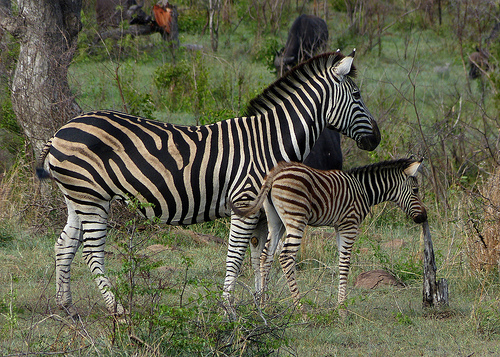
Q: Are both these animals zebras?
A: Yes, all the animals are zebras.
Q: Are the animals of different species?
A: No, all the animals are zebras.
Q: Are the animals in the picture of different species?
A: No, all the animals are zebras.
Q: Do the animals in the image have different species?
A: No, all the animals are zebras.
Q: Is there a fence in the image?
A: No, there are no fences.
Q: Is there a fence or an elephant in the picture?
A: No, there are no fences or elephants.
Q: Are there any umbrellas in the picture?
A: No, there are no umbrellas.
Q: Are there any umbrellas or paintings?
A: No, there are no umbrellas or paintings.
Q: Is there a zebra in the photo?
A: Yes, there is a zebra.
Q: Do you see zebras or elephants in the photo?
A: Yes, there is a zebra.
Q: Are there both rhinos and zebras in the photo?
A: No, there is a zebra but no rhinos.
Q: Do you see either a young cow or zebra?
A: Yes, there is a young zebra.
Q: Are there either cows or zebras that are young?
A: Yes, the zebra is young.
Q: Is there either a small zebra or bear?
A: Yes, there is a small zebra.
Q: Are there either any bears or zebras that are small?
A: Yes, the zebra is small.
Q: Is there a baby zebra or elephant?
A: Yes, there is a baby zebra.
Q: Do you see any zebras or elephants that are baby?
A: Yes, the zebra is a baby.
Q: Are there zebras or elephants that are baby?
A: Yes, the zebra is a baby.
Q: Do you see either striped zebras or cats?
A: Yes, there is a striped zebra.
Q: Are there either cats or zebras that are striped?
A: Yes, the zebra is striped.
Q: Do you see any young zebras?
A: Yes, there is a young zebra.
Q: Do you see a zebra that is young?
A: Yes, there is a zebra that is young.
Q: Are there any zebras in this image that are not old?
A: Yes, there is an young zebra.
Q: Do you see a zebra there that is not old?
A: Yes, there is an young zebra.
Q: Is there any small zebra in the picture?
A: Yes, there is a small zebra.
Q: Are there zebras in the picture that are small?
A: Yes, there is a zebra that is small.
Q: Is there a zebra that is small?
A: Yes, there is a zebra that is small.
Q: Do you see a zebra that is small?
A: Yes, there is a zebra that is small.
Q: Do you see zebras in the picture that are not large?
A: Yes, there is a small zebra.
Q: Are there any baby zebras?
A: Yes, there is a baby zebra.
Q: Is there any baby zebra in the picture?
A: Yes, there is a baby zebra.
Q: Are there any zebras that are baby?
A: Yes, there is a zebra that is a baby.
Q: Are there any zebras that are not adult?
A: Yes, there is an baby zebra.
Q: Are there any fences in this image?
A: No, there are no fences.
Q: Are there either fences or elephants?
A: No, there are no fences or elephants.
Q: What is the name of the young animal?
A: The animal is a zebra.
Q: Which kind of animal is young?
A: The animal is a zebra.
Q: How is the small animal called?
A: The animal is a zebra.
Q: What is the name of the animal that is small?
A: The animal is a zebra.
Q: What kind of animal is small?
A: The animal is a zebra.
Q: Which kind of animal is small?
A: The animal is a zebra.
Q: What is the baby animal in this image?
A: The animal is a zebra.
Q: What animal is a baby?
A: The animal is a zebra.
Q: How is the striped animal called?
A: The animal is a zebra.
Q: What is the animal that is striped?
A: The animal is a zebra.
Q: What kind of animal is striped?
A: The animal is a zebra.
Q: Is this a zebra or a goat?
A: This is a zebra.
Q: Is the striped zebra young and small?
A: Yes, the zebra is young and small.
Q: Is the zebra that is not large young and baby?
A: Yes, the zebra is young and baby.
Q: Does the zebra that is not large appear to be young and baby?
A: Yes, the zebra is young and baby.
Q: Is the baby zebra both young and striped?
A: Yes, the zebra is young and striped.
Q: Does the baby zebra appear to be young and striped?
A: Yes, the zebra is young and striped.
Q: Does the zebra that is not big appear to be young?
A: Yes, the zebra is young.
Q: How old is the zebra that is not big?
A: The zebra is young.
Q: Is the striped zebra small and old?
A: No, the zebra is small but young.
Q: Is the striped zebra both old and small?
A: No, the zebra is small but young.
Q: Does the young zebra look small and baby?
A: Yes, the zebra is small and baby.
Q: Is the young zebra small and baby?
A: Yes, the zebra is small and baby.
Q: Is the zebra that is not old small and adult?
A: No, the zebra is small but baby.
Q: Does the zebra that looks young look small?
A: Yes, the zebra is small.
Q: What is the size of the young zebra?
A: The zebra is small.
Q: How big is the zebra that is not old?
A: The zebra is small.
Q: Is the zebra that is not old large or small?
A: The zebra is small.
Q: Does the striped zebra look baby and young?
A: Yes, the zebra is a baby and young.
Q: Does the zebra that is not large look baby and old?
A: No, the zebra is a baby but young.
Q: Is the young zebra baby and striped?
A: Yes, the zebra is a baby and striped.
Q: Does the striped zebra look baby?
A: Yes, the zebra is a baby.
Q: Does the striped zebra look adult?
A: No, the zebra is a baby.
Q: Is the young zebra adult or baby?
A: The zebra is a baby.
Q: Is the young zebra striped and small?
A: Yes, the zebra is striped and small.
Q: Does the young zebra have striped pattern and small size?
A: Yes, the zebra is striped and small.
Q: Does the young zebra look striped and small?
A: Yes, the zebra is striped and small.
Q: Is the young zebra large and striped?
A: No, the zebra is striped but small.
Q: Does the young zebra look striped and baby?
A: Yes, the zebra is striped and baby.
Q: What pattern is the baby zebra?
A: The zebra is striped.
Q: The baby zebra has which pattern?
A: The zebra is striped.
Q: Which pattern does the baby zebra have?
A: The zebra has striped pattern.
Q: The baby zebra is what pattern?
A: The zebra is striped.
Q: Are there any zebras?
A: Yes, there is a zebra.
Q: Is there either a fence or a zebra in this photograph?
A: Yes, there is a zebra.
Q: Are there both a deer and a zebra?
A: No, there is a zebra but no deer.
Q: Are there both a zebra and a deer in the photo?
A: No, there is a zebra but no deer.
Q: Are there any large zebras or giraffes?
A: Yes, there is a large zebra.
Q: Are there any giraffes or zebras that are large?
A: Yes, the zebra is large.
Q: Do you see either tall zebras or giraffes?
A: Yes, there is a tall zebra.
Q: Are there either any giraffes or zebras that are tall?
A: Yes, the zebra is tall.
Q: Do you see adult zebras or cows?
A: Yes, there is an adult zebra.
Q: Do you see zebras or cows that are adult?
A: Yes, the zebra is adult.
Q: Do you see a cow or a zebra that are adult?
A: Yes, the zebra is adult.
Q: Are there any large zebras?
A: Yes, there is a large zebra.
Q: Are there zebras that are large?
A: Yes, there is a zebra that is large.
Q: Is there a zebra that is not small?
A: Yes, there is a large zebra.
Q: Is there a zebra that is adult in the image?
A: Yes, there is an adult zebra.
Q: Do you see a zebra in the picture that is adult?
A: Yes, there is a zebra that is adult.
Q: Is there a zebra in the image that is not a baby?
A: Yes, there is a adult zebra.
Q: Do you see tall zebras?
A: Yes, there is a tall zebra.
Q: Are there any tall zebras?
A: Yes, there is a tall zebra.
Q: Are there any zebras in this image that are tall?
A: Yes, there is a zebra that is tall.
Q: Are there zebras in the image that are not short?
A: Yes, there is a tall zebra.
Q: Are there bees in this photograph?
A: No, there are no bees.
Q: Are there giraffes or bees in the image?
A: No, there are no bees or giraffes.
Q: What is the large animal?
A: The animal is a zebra.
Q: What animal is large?
A: The animal is a zebra.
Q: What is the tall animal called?
A: The animal is a zebra.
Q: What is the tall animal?
A: The animal is a zebra.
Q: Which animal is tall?
A: The animal is a zebra.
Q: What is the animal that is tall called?
A: The animal is a zebra.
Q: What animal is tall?
A: The animal is a zebra.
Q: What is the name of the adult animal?
A: The animal is a zebra.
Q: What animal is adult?
A: The animal is a zebra.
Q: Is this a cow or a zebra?
A: This is a zebra.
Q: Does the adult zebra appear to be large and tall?
A: Yes, the zebra is large and tall.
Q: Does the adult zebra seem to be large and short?
A: No, the zebra is large but tall.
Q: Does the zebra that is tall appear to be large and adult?
A: Yes, the zebra is large and adult.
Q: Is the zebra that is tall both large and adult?
A: Yes, the zebra is large and adult.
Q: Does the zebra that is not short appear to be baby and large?
A: No, the zebra is large but adult.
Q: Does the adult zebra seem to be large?
A: Yes, the zebra is large.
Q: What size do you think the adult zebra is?
A: The zebra is large.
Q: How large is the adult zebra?
A: The zebra is large.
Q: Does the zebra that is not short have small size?
A: No, the zebra is large.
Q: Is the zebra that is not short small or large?
A: The zebra is large.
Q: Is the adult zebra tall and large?
A: Yes, the zebra is tall and large.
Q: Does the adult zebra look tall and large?
A: Yes, the zebra is tall and large.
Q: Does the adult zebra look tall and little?
A: No, the zebra is tall but large.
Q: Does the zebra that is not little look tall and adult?
A: Yes, the zebra is tall and adult.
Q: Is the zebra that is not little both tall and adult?
A: Yes, the zebra is tall and adult.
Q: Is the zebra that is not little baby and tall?
A: No, the zebra is tall but adult.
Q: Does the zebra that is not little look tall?
A: Yes, the zebra is tall.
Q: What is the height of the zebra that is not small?
A: The zebra is tall.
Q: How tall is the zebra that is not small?
A: The zebra is tall.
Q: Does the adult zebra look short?
A: No, the zebra is tall.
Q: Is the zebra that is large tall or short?
A: The zebra is tall.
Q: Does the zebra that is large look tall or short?
A: The zebra is tall.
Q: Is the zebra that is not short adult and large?
A: Yes, the zebra is adult and large.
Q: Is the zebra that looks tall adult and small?
A: No, the zebra is adult but large.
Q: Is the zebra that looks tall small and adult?
A: No, the zebra is adult but large.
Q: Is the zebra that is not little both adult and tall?
A: Yes, the zebra is adult and tall.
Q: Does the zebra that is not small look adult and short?
A: No, the zebra is adult but tall.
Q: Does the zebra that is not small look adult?
A: Yes, the zebra is adult.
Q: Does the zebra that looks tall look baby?
A: No, the zebra is adult.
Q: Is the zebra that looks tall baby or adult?
A: The zebra is adult.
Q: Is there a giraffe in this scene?
A: No, there are no giraffes.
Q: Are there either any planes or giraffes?
A: No, there are no giraffes or planes.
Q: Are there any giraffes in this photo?
A: No, there are no giraffes.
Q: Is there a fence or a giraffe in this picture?
A: No, there are no giraffes or fences.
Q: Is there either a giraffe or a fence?
A: No, there are no giraffes or fences.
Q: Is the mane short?
A: Yes, the mane is short.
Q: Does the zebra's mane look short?
A: Yes, the mane is short.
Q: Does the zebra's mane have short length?
A: Yes, the mane is short.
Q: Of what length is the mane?
A: The mane is short.